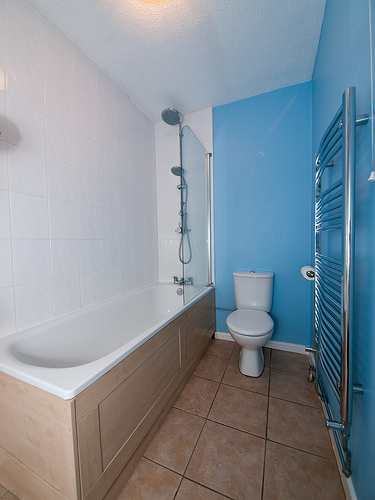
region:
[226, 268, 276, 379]
white porcelain toilet in bathroom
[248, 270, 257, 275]
push button to flush toilet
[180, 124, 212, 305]
glass divider for shower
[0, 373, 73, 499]
wooden enclosure for end of bathtub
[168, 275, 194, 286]
faucet for bathtub and shower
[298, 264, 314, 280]
roll of white toilet paper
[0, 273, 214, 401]
long white bath tub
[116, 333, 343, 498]
ceramic tile floor in bathroom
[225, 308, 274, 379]
base of white toilet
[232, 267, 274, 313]
tank of white toilet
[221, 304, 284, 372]
the toilet cover is down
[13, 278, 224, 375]
the tub is empty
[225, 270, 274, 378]
the white toilet bowl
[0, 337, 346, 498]
the tiles on the ground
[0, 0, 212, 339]
the tiles on the wall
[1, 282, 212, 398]
the white bath tub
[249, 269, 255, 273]
the flush buttons on the toilet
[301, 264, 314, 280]
the roll of toilet paper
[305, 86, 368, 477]
the metal object on the wall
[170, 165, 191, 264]
the detachable shower head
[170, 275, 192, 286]
the water fixtures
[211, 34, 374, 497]
the blue colored walls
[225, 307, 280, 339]
A closed toilet lid.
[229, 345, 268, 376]
The bottom portion of a toilet.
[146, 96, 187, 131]
The top portion of a showerhead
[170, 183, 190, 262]
The body of a small showerhead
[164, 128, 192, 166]
The body of a large showerhead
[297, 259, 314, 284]
A small roll of toilet paper.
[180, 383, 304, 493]
A portion of tiled flooring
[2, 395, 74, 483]
A small wooden portion of a bath tub.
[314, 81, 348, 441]
A wired metal framework hanging off of a blue wall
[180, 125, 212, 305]
A piece of a glass wall.